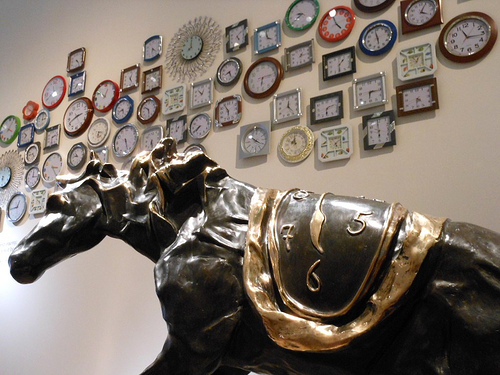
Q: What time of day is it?
A: Day time.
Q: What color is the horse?
A: Black.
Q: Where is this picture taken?
A: Museum.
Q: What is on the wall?
A: Clocks.